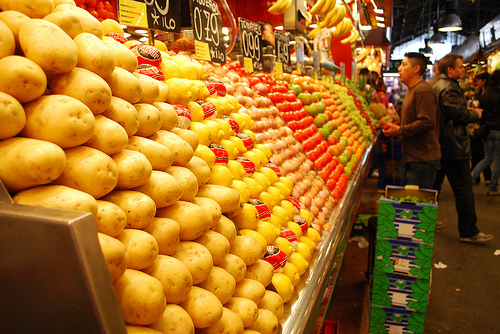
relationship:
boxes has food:
[374, 220, 442, 333] [393, 187, 432, 203]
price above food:
[192, 12, 267, 64] [132, 47, 378, 195]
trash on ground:
[438, 256, 451, 279] [442, 233, 499, 321]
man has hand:
[375, 53, 440, 174] [389, 120, 400, 141]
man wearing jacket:
[437, 57, 462, 153] [439, 84, 467, 150]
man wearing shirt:
[375, 53, 440, 174] [401, 97, 437, 156]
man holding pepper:
[375, 53, 440, 174] [383, 121, 406, 132]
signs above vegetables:
[188, 13, 321, 78] [168, 72, 373, 189]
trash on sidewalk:
[438, 256, 451, 279] [442, 233, 499, 321]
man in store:
[375, 53, 440, 174] [311, 16, 493, 317]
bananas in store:
[305, 3, 359, 46] [311, 16, 493, 317]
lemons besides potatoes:
[215, 143, 275, 203] [126, 190, 231, 304]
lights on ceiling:
[396, 35, 469, 62] [396, 4, 499, 35]